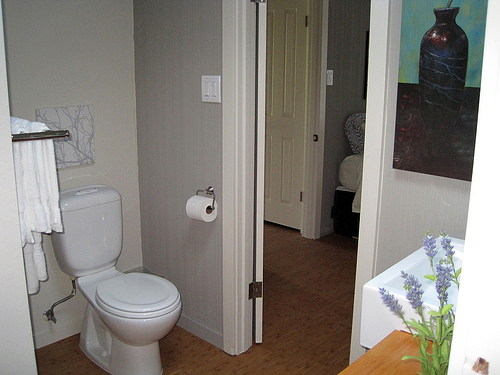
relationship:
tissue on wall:
[183, 194, 217, 222] [133, 2, 223, 352]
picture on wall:
[34, 105, 95, 168] [0, 1, 144, 354]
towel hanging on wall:
[12, 116, 62, 305] [2, 2, 39, 374]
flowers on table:
[375, 229, 458, 375] [332, 329, 451, 374]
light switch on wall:
[199, 75, 224, 105] [133, 2, 223, 352]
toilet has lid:
[25, 119, 225, 370] [95, 271, 180, 315]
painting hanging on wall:
[34, 105, 95, 168] [0, 1, 144, 354]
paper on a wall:
[183, 194, 217, 222] [133, 2, 223, 352]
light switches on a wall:
[199, 75, 224, 105] [133, 2, 223, 352]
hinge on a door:
[248, 281, 262, 300] [252, 4, 264, 345]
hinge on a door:
[249, 1, 266, 4] [252, 4, 264, 345]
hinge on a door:
[297, 191, 303, 204] [265, 0, 320, 230]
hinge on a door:
[303, 14, 310, 28] [265, 0, 320, 230]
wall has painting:
[362, 21, 496, 198] [391, 0, 476, 182]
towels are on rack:
[8, 116, 93, 278] [8, 116, 93, 278]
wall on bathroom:
[302, 4, 393, 202] [302, 4, 393, 202]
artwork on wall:
[398, 19, 493, 153] [398, 19, 493, 153]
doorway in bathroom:
[216, 49, 446, 346] [216, 49, 446, 346]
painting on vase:
[379, 17, 499, 171] [379, 17, 499, 171]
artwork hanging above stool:
[28, 107, 113, 165] [28, 107, 192, 365]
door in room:
[242, 16, 384, 267] [242, 16, 384, 267]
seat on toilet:
[52, 183, 209, 334] [52, 183, 209, 334]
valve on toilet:
[28, 254, 92, 345] [28, 184, 215, 345]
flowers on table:
[352, 236, 496, 371] [352, 236, 496, 371]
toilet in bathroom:
[25, 119, 225, 370] [25, 119, 225, 370]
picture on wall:
[382, 17, 489, 187] [382, 17, 489, 187]